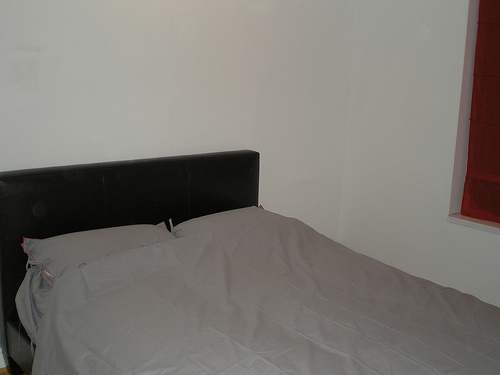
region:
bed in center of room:
[3, 149, 498, 374]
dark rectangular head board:
[2, 147, 257, 321]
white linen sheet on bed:
[33, 214, 498, 373]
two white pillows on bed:
[18, 203, 283, 290]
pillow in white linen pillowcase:
[17, 221, 178, 286]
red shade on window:
[460, 2, 499, 226]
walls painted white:
[2, 2, 497, 306]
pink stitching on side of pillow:
[20, 242, 57, 291]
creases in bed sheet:
[278, 290, 475, 372]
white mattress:
[2, 315, 37, 368]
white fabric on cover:
[250, 233, 316, 293]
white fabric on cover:
[80, 304, 120, 323]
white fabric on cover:
[166, 317, 231, 356]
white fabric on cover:
[229, 337, 292, 362]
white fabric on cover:
[275, 325, 330, 346]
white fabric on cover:
[333, 302, 389, 340]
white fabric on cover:
[385, 302, 438, 337]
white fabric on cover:
[434, 319, 483, 358]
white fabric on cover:
[175, 242, 235, 282]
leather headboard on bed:
[1, 141, 270, 326]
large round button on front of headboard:
[22, 189, 61, 226]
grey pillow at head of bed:
[18, 214, 189, 291]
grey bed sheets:
[7, 201, 496, 373]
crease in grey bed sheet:
[170, 294, 292, 373]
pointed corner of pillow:
[148, 213, 175, 235]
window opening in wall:
[444, 38, 499, 258]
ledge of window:
[442, 197, 499, 239]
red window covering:
[454, 41, 499, 236]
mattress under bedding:
[3, 320, 42, 373]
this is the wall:
[277, 20, 380, 140]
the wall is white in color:
[301, 94, 368, 180]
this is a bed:
[103, 159, 213, 202]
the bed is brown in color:
[118, 154, 171, 200]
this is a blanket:
[233, 264, 340, 358]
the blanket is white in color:
[233, 196, 347, 316]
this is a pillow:
[33, 239, 82, 249]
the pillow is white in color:
[46, 238, 106, 270]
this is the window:
[475, 35, 492, 194]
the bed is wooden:
[78, 157, 152, 184]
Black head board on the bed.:
[50, 117, 249, 247]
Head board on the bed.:
[3, 97, 326, 297]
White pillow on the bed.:
[0, 223, 192, 292]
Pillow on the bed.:
[16, 222, 242, 300]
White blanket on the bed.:
[64, 227, 306, 358]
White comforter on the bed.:
[56, 199, 206, 362]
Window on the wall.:
[424, 49, 498, 249]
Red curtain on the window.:
[435, 79, 499, 170]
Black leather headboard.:
[74, 144, 292, 288]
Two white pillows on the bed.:
[32, 204, 426, 327]